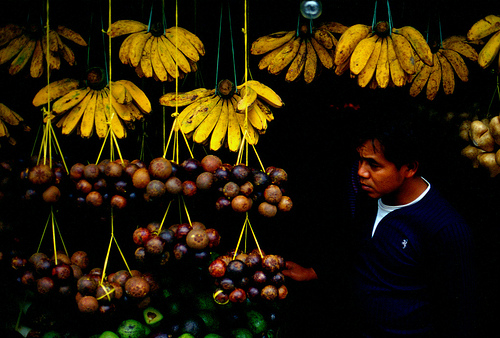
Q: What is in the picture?
A: Fruits.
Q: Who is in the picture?
A: A man.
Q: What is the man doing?
A: Looking at the fruits.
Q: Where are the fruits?
A: Hanging from the ceiling.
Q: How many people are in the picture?
A: One.